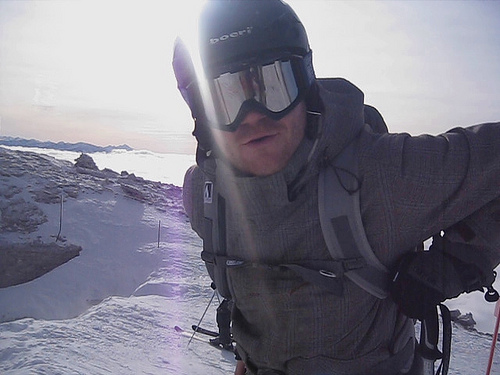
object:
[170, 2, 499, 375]
man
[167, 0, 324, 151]
helmet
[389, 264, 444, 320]
gloves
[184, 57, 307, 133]
goggles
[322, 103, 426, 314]
backpack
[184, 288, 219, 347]
ski pole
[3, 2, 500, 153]
sky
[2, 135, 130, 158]
mountains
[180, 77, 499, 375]
jacket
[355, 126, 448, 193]
shoulder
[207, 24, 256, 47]
writing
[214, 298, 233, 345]
pants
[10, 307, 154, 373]
snow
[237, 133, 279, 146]
lips